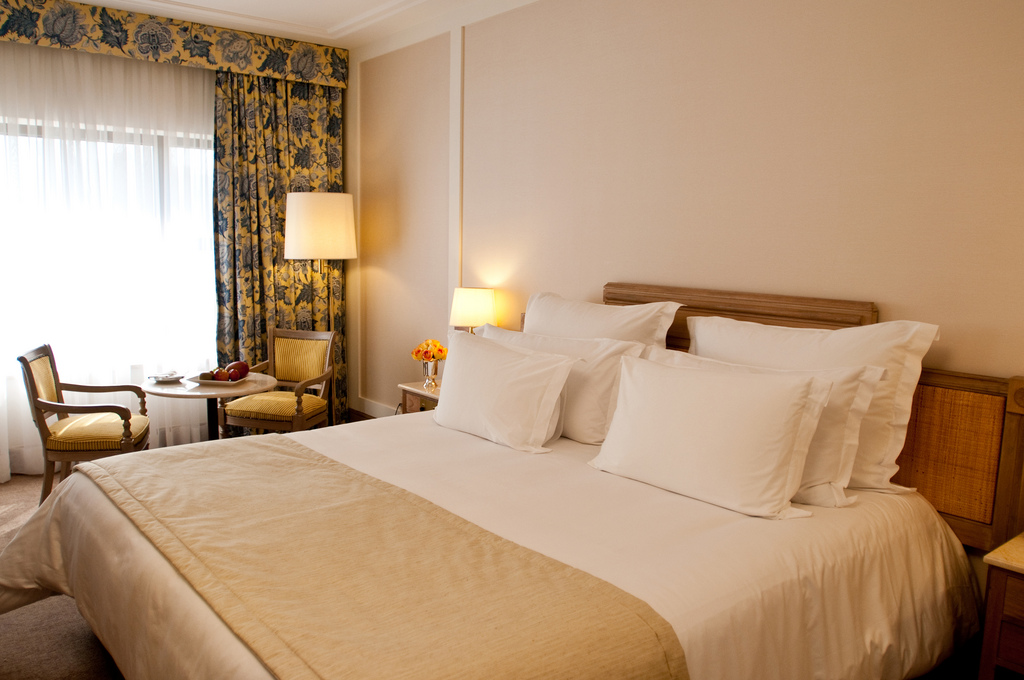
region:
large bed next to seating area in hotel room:
[14, 17, 1010, 666]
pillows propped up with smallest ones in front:
[428, 288, 934, 519]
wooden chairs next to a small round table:
[16, 327, 340, 477]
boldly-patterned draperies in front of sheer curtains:
[9, 14, 351, 470]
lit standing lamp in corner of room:
[276, 187, 362, 423]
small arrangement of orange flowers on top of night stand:
[411, 335, 449, 400]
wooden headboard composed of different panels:
[598, 275, 1017, 574]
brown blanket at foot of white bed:
[13, 361, 978, 672]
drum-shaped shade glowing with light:
[447, 282, 524, 328]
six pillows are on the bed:
[438, 284, 925, 566]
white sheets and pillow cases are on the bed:
[313, 290, 965, 677]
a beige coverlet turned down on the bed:
[5, 432, 698, 677]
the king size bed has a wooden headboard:
[514, 269, 1017, 631]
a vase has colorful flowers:
[404, 334, 450, 396]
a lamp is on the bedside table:
[398, 274, 523, 433]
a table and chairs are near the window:
[19, 319, 336, 475]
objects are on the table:
[141, 356, 278, 413]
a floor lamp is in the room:
[277, 181, 363, 445]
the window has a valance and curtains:
[3, 0, 354, 428]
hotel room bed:
[48, 275, 1013, 677]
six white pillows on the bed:
[437, 290, 938, 507]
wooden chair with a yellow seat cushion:
[19, 342, 147, 501]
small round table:
[146, 361, 276, 441]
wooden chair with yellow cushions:
[229, 334, 344, 424]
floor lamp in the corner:
[283, 190, 356, 327]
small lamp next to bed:
[444, 287, 524, 329]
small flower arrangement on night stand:
[412, 339, 444, 396]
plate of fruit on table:
[194, 361, 253, 385]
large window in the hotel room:
[1, 3, 349, 472]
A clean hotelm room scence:
[22, 10, 1007, 656]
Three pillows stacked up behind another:
[620, 309, 938, 519]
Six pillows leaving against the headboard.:
[442, 288, 945, 498]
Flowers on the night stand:
[407, 332, 449, 396]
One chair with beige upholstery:
[8, 332, 155, 472]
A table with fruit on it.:
[189, 341, 272, 398]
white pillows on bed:
[412, 320, 640, 450]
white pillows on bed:
[637, 294, 914, 513]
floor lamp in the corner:
[263, 145, 378, 364]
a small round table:
[139, 353, 270, 434]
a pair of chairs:
[0, 293, 334, 468]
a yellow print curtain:
[180, 69, 361, 403]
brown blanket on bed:
[117, 386, 665, 677]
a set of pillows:
[411, 222, 928, 530]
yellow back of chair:
[257, 339, 333, 381]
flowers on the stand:
[396, 322, 448, 402]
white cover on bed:
[306, 398, 901, 674]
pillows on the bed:
[364, 206, 962, 521]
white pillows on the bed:
[359, 209, 989, 529]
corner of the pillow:
[844, 279, 984, 406]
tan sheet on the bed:
[163, 432, 452, 642]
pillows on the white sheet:
[142, 206, 1013, 592]